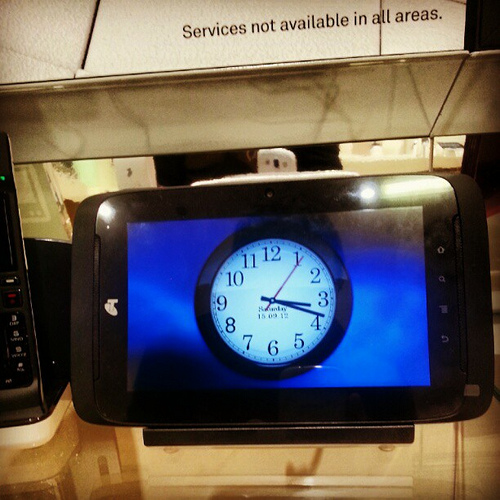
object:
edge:
[286, 365, 323, 384]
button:
[438, 246, 445, 253]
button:
[439, 276, 445, 282]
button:
[439, 305, 448, 314]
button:
[442, 336, 449, 343]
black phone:
[70, 171, 494, 427]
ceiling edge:
[0, 48, 497, 95]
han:
[261, 296, 327, 318]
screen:
[125, 207, 429, 389]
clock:
[197, 222, 354, 378]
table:
[0, 398, 500, 500]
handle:
[142, 427, 417, 447]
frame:
[194, 221, 355, 382]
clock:
[192, 222, 355, 382]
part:
[386, 328, 413, 356]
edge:
[118, 421, 440, 433]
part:
[267, 327, 304, 365]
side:
[422, 173, 494, 422]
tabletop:
[1, 63, 500, 244]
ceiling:
[0, 48, 500, 168]